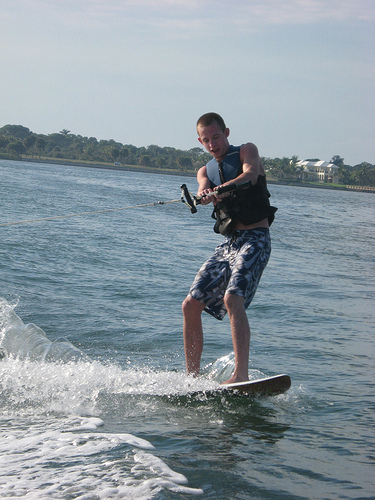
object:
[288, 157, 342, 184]
house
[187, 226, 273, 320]
shorts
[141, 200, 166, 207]
chord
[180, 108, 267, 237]
grandfather clock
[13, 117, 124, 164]
dense trees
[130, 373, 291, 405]
board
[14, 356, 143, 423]
wave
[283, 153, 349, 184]
building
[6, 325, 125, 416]
plastic bags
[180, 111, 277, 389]
boy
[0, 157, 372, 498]
water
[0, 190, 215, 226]
rope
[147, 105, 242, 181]
wake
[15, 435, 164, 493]
foamy water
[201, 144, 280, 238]
vest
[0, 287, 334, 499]
foam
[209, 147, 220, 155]
mouth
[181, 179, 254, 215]
grip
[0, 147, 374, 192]
shore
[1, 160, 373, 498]
lake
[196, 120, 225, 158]
face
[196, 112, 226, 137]
hair